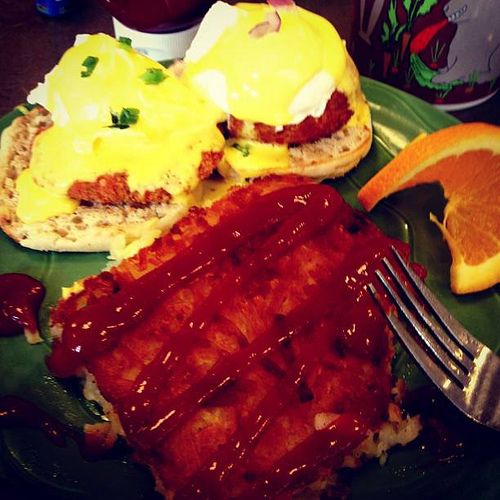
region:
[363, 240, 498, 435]
the tines of a fork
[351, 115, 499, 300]
a slice of orange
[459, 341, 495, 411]
light shining on the fork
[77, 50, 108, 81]
a slice of green onion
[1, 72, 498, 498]
a green porcelain plate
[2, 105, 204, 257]
a white biscuit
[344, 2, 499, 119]
a painted coffee mug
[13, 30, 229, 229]
yellow cheese sauce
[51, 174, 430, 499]
hash browns on the plate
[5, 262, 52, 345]
ketchup on the plate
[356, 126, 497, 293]
orange on green plate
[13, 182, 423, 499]
barbeque spareribs on green plate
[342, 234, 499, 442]
silver fork on green plate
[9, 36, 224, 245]
food on english muffin with yellow sauce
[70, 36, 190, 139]
green onions on yellow sauce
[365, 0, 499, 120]
child's purple drinking cup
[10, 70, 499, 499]
green plate with food on it.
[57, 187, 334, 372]
red barbeque sauce on ribs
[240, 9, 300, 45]
mushroom on yellow sauce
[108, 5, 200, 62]
white cup with lid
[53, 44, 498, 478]
A delicious looking breakfast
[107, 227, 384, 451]
Hash browns on a green plate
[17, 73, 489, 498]
A green plate below food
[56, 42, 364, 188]
A breakfast sandwich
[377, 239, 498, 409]
A metal fork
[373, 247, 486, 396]
The fork has four prongs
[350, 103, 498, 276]
A slice of an orange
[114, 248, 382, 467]
Ketchup drizzled over hash browns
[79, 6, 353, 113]
Eggs on the breakfast sandwich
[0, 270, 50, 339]
A dollop of ketchup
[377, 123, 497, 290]
slice of orange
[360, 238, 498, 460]
silver dinner fork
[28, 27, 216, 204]
yellow sauce on a patty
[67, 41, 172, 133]
green onions on yellow sauce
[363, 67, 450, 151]
green dinner plate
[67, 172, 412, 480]
hash brown potatoes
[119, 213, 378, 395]
ketchup on hash browns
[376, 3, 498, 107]
plastic drinking glass in upper right corner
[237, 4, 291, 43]
chopped red onion atop yellow sauce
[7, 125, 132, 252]
English muffin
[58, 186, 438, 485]
the food has ketchup on it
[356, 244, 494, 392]
fork is on the plate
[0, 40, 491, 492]
the plate is green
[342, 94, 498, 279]
an orange is on edge of plate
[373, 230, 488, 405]
fork made of metal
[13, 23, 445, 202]
bagels covered in yellow food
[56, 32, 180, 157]
green herb on food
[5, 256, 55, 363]
ketchup is on plate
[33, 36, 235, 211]
egg is covering food underneath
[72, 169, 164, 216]
the food is brown